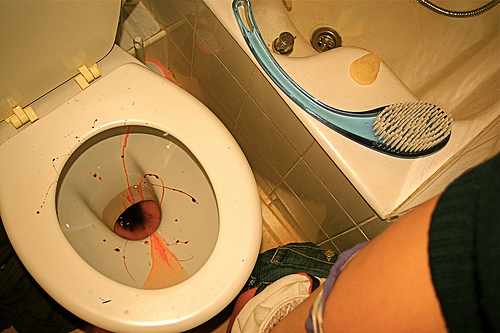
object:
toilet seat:
[215, 178, 251, 238]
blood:
[117, 185, 169, 267]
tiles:
[231, 68, 314, 151]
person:
[270, 152, 497, 332]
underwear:
[303, 237, 371, 331]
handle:
[130, 35, 153, 65]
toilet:
[0, 0, 261, 330]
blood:
[94, 175, 165, 237]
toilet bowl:
[52, 125, 222, 290]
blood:
[93, 170, 95, 178]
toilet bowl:
[24, 112, 224, 298]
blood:
[114, 202, 148, 233]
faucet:
[276, 14, 350, 61]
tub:
[278, 7, 456, 121]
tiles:
[127, 0, 401, 266]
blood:
[105, 176, 146, 233]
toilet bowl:
[1, 55, 264, 329]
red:
[88, 148, 182, 241]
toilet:
[0, 120, 265, 325]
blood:
[35, 154, 60, 214]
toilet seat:
[0, 62, 264, 331]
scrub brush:
[233, 1, 453, 160]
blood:
[109, 170, 199, 268]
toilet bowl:
[21, 112, 268, 313]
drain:
[274, 20, 342, 52]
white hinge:
[74, 62, 106, 89]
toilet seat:
[113, 64, 189, 131]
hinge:
[9, 97, 40, 139]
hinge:
[72, 52, 101, 88]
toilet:
[1, 40, 231, 312]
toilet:
[18, 124, 262, 312]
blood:
[94, 147, 165, 271]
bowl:
[0, 46, 265, 324]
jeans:
[264, 254, 327, 278]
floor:
[266, 195, 301, 252]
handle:
[230, 0, 372, 147]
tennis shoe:
[231, 270, 328, 330]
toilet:
[0, 52, 272, 326]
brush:
[238, 5, 459, 158]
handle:
[233, 3, 373, 136]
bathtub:
[141, 0, 498, 260]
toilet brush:
[132, 32, 167, 79]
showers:
[360, 28, 492, 185]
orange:
[87, 124, 202, 290]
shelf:
[204, 0, 497, 220]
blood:
[80, 127, 198, 289]